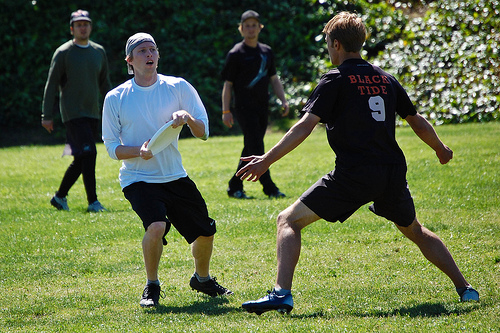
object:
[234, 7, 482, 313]
man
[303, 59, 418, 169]
shirt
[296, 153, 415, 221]
shorts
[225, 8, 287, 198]
man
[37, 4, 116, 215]
person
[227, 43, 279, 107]
tshirt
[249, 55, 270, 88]
blue design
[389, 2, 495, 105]
plant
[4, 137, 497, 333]
field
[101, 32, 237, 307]
man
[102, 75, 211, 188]
white shirt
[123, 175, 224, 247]
black shorts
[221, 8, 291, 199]
person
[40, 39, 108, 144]
shirt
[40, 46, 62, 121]
sleeve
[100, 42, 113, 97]
sleeve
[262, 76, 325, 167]
arms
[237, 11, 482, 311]
person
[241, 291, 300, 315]
shoe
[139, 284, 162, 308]
shoe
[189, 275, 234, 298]
shoe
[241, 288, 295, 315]
foot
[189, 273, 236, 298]
foot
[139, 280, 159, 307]
foot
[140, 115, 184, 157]
frisbee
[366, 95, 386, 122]
9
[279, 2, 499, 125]
bush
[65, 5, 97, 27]
cap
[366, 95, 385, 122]
number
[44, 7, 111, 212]
man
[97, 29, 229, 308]
frisbee holder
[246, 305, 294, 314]
cleats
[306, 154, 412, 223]
pants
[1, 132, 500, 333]
grass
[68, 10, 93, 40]
head